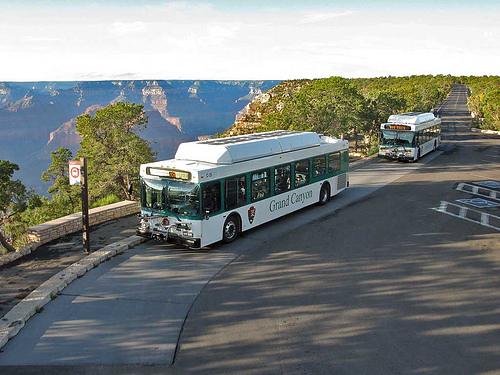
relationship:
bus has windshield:
[129, 125, 356, 251] [140, 175, 164, 210]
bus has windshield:
[129, 125, 356, 251] [166, 184, 197, 215]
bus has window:
[129, 125, 356, 251] [329, 153, 343, 175]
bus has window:
[129, 125, 356, 251] [311, 157, 327, 178]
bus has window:
[129, 125, 356, 251] [293, 162, 309, 189]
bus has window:
[129, 125, 356, 251] [275, 165, 293, 192]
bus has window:
[129, 125, 356, 251] [248, 172, 270, 198]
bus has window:
[129, 125, 356, 251] [224, 178, 246, 206]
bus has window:
[129, 125, 356, 251] [202, 186, 222, 212]